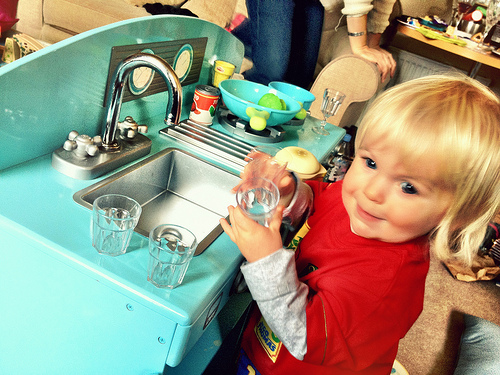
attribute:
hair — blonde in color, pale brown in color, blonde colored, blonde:
[351, 71, 497, 267]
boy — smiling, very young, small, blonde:
[229, 68, 497, 371]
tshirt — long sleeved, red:
[243, 177, 432, 374]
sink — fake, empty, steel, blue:
[85, 150, 256, 248]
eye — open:
[396, 177, 422, 197]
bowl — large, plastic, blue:
[218, 83, 301, 130]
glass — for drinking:
[149, 224, 195, 286]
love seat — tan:
[11, 0, 237, 63]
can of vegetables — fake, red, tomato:
[189, 84, 223, 127]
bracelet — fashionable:
[346, 30, 369, 39]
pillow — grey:
[451, 311, 499, 374]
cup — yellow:
[213, 62, 235, 85]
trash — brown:
[443, 249, 498, 283]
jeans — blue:
[229, 0, 329, 83]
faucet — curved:
[106, 52, 184, 160]